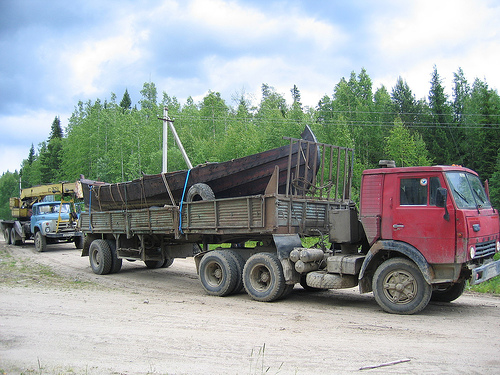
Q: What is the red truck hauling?
A: Boat.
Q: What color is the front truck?
A: Red.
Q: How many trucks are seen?
A: 2.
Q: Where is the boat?
A: On the trailer.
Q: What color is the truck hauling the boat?
A: Red.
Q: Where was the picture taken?
A: Forest.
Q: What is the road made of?
A: Dirt.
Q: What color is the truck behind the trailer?
A: Blue.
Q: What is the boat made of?
A: Wood.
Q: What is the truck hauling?
A: A boat.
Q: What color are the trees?
A: Green.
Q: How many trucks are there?
A: 2.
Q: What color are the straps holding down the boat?
A: Blue.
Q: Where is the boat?
A: On the trailer.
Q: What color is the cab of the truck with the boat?
A: Red.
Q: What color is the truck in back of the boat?
A: Blue.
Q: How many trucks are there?
A: 2.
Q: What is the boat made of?
A: Wood.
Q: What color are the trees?
A: Green.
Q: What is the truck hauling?
A: Boat.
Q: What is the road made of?
A: Dirt.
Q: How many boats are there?
A: 1.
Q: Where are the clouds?
A: In the sky.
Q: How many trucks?
A: Two.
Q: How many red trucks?
A: One.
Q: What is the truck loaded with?
A: Boat.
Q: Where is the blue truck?
A: Behind the red truck.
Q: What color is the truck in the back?
A: Blue.